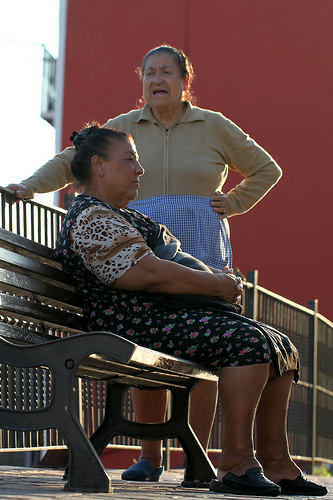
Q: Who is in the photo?
A: Two women .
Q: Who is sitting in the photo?
A: The woman in the black dress.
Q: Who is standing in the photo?
A: The woman wearing an apron.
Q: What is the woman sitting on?
A: A park bench.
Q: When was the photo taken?
A: During the day time.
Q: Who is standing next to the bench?
A: A woman.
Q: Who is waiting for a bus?
A: A woman.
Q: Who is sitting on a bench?
A: A woman.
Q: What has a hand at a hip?
A: A woman.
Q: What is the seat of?
A: A bench.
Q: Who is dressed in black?
A: A woman.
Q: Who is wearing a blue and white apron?
A: The woman standing up.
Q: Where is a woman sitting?
A: On a bench.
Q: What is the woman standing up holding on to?
A: Black railing.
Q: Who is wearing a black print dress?
A: Woman sitting on bench.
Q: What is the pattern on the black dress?
A: Flowers.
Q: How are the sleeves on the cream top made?
A: Long sleeves.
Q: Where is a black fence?
A: Behind the bench.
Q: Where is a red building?
A: Behind the two women.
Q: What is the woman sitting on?
A: A bench.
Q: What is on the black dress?
A: Flowers.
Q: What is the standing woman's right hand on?
A: A railing.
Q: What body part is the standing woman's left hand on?
A: Hip.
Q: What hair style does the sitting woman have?
A: A bun.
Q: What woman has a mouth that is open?
A: The standing woman.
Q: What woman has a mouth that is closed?
A: The sitting woman.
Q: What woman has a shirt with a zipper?
A: The standing woman.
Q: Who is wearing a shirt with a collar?
A: The standing woman.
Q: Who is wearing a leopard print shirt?
A: The sitting woman.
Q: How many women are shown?
A: Two.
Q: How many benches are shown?
A: One.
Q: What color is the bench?
A: Black.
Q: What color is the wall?
A: Red.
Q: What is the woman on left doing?
A: Sitting.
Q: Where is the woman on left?
A: The bench.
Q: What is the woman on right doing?
A: Standing.